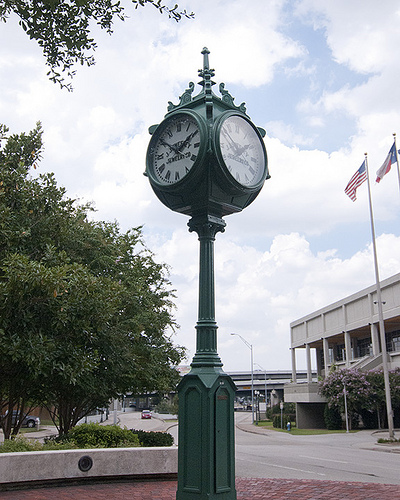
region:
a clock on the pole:
[149, 112, 201, 184]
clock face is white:
[219, 113, 265, 187]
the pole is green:
[144, 44, 271, 498]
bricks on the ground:
[2, 476, 399, 497]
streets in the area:
[0, 410, 399, 482]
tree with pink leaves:
[320, 365, 397, 414]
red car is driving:
[140, 409, 150, 418]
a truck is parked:
[1, 409, 39, 427]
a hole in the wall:
[78, 454, 92, 471]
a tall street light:
[230, 332, 254, 422]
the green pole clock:
[142, 47, 270, 499]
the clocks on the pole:
[146, 109, 267, 189]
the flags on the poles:
[344, 132, 399, 441]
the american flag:
[343, 159, 367, 202]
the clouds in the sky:
[0, 0, 399, 369]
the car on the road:
[141, 408, 152, 418]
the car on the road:
[0, 409, 40, 427]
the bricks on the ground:
[0, 476, 398, 498]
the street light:
[230, 332, 254, 423]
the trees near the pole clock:
[0, 1, 196, 443]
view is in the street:
[67, 207, 395, 472]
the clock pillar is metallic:
[182, 154, 225, 470]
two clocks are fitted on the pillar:
[140, 88, 310, 250]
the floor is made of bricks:
[284, 467, 332, 497]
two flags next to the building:
[340, 147, 398, 272]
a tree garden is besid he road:
[23, 184, 166, 482]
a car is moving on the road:
[129, 402, 178, 444]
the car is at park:
[6, 394, 70, 451]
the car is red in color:
[130, 391, 159, 448]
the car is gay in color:
[7, 398, 69, 456]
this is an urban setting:
[27, 22, 335, 406]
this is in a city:
[23, 93, 380, 462]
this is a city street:
[67, 301, 377, 489]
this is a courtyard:
[23, 96, 331, 462]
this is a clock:
[136, 95, 243, 213]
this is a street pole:
[161, 93, 255, 465]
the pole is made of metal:
[143, 78, 292, 472]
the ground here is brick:
[80, 469, 153, 497]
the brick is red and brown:
[244, 476, 302, 499]